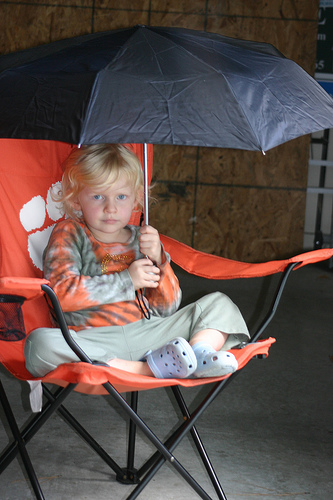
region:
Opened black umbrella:
[8, 21, 327, 165]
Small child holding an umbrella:
[43, 122, 261, 341]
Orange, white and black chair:
[5, 145, 76, 412]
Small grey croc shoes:
[131, 325, 244, 397]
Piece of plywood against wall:
[174, 146, 330, 235]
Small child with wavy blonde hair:
[42, 146, 152, 270]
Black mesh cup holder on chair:
[0, 282, 41, 347]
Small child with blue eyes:
[80, 179, 138, 247]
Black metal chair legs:
[11, 388, 230, 498]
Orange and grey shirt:
[50, 218, 130, 323]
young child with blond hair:
[57, 143, 154, 237]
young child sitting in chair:
[39, 143, 240, 386]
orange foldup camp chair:
[0, 134, 286, 401]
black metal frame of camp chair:
[14, 378, 235, 485]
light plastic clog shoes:
[131, 335, 242, 385]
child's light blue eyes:
[83, 184, 133, 207]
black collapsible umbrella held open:
[3, 24, 327, 180]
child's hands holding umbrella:
[129, 219, 171, 295]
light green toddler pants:
[18, 281, 253, 382]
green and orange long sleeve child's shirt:
[40, 215, 183, 322]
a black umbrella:
[0, 22, 332, 155]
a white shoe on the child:
[143, 336, 198, 385]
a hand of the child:
[124, 252, 173, 297]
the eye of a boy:
[114, 190, 132, 203]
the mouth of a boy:
[98, 214, 124, 230]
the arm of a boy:
[40, 222, 134, 311]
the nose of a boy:
[99, 195, 121, 215]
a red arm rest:
[145, 224, 331, 282]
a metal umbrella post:
[138, 138, 161, 231]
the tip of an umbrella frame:
[258, 146, 269, 158]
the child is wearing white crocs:
[132, 329, 260, 380]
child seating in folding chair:
[10, 295, 283, 410]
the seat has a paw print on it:
[2, 165, 103, 325]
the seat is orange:
[2, 224, 216, 406]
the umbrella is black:
[32, 15, 331, 196]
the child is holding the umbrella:
[119, 95, 190, 310]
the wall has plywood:
[60, 5, 331, 35]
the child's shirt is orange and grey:
[43, 234, 215, 324]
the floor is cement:
[240, 308, 327, 472]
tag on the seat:
[19, 375, 56, 421]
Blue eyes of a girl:
[90, 192, 130, 201]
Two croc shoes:
[142, 333, 238, 381]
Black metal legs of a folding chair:
[0, 381, 232, 499]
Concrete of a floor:
[224, 409, 321, 486]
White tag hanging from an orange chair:
[19, 376, 45, 410]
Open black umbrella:
[3, 23, 330, 147]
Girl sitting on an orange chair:
[42, 139, 246, 380]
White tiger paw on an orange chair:
[15, 179, 87, 282]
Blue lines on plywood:
[184, 181, 305, 260]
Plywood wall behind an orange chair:
[0, 33, 313, 168]